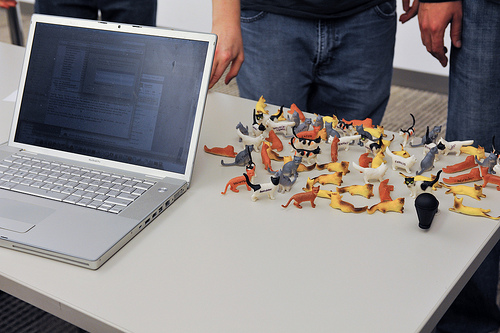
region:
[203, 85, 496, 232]
collection of small plastic cats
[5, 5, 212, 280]
open laptop with screen showing text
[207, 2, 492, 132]
two people wearing jeans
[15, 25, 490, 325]
long grey table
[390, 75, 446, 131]
patterned tan and brown rug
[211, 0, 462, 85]
hands on side of pants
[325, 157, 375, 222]
yellow and brown cats laying down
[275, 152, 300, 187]
grey cat sitting on hind legs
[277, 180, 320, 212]
brown cat standing on all fours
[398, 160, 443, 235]
black and white cat looking at round and black object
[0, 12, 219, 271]
A silver laptop computer in use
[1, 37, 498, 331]
A long white table holding a computer and figurines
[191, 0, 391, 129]
A man standing with his hand on the table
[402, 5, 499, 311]
A man standing beside the other man behind the table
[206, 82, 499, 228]
A mass of cat figurines on top of the table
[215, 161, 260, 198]
A small orange cat figurine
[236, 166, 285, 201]
A small black and white cat figurine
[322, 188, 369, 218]
A small figurine of an Abyssinian cat lying down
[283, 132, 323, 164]
Two small figurines of calico cats with their tails up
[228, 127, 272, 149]
A figurine of a white cat with long fur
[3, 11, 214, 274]
a silver metal laptop computer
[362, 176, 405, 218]
a small action figure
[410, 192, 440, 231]
a small action figure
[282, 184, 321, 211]
a small cat figurine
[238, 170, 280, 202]
a small cat figurine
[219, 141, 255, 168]
a small cat figurine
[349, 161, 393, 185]
a small cat figurine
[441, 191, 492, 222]
a small cat figurine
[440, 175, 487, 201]
a small cat figurine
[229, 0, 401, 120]
a pair of blue jeans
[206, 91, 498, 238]
The animal figurines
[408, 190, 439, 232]
The large black animal figurine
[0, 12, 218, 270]
The silver laptop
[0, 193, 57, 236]
The mousepad on the laptop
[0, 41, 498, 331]
The table in the photo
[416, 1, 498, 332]
The person furthest to the right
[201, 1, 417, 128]
The person in the middle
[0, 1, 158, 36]
The person on the left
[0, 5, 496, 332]
The carpet on the ground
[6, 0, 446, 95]
The baseboard on the wall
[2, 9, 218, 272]
open silver laptop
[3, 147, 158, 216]
silver laptop keyboard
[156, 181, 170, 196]
silver laptop power button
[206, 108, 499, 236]
group of plastic toy figurines on top of white desk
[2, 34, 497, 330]
white rectangular table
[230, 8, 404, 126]
pair of blue denim jeans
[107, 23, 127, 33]
silver laptop camera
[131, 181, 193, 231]
silver laptop extension inputs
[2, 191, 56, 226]
silver laptop track pad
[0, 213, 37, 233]
silver laptop spacebar